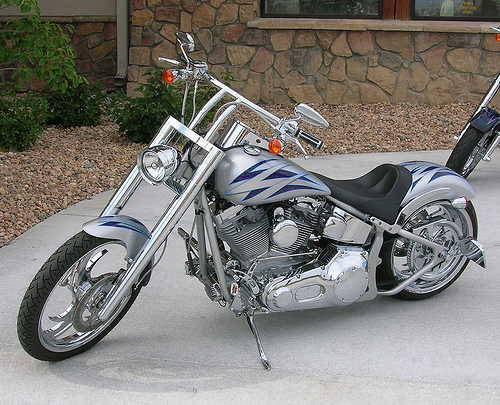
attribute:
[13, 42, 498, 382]
motorcycle — silver, blue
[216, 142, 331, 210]
designs — blue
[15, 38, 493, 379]
bike — blue, silver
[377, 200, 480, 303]
wheel — back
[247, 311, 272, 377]
kick stand — metal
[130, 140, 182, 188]
light — white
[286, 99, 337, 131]
mirror — left-hand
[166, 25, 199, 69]
mirror — right-hand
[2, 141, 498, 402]
ground — gray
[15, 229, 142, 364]
tire — black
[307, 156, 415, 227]
seat — black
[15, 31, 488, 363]
motorcycle — glossy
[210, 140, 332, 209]
gas tank — gray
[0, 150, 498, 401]
driveway — gray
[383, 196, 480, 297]
tire — black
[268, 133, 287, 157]
light — orange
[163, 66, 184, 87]
light — orange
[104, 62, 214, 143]
plant — green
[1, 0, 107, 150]
plant — green